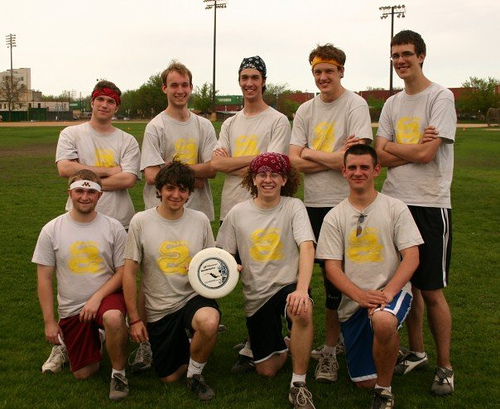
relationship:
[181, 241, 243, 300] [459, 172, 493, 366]
frisbee above grass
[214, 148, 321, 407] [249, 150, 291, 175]
man wears bandana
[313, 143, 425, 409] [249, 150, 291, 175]
boys wears bandana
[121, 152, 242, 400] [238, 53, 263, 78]
man wears bandana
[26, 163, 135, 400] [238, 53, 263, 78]
man wears bandana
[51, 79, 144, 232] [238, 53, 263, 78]
man wears bandana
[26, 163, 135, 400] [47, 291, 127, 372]
man wears shorts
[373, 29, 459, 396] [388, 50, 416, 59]
man wears glasses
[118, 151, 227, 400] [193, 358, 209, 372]
man wears socks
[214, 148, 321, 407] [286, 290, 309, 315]
man shows hand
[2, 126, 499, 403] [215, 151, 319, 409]
field under man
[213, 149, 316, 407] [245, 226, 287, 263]
shirt has writing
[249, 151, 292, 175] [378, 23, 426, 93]
bandana on head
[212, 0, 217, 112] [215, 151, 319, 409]
pole behind man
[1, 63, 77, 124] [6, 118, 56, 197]
building near lawn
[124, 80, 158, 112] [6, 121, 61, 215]
trees near ground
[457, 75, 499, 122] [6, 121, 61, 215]
trees near ground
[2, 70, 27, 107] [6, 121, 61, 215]
trees near ground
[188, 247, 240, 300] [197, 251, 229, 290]
frisbee has markings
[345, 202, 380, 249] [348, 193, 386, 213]
sunglasses on collar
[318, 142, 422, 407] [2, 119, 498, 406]
boys in grass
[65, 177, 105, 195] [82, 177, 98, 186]
sweatband with letter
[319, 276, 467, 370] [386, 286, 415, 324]
shorts with stripes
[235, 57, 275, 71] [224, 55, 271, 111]
bandana on head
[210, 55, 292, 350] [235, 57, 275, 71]
green guy wearing bandana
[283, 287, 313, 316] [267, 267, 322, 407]
hand on knee